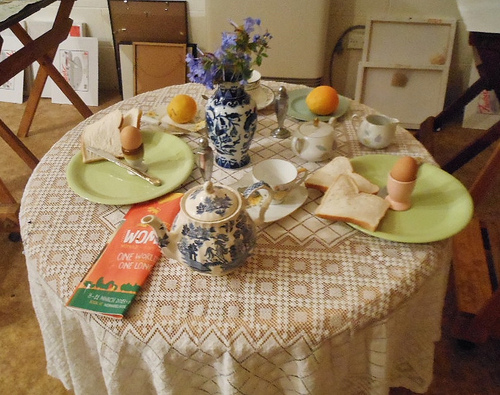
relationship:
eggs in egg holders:
[389, 150, 416, 181] [124, 146, 146, 170]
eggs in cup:
[119, 122, 141, 149] [384, 172, 416, 211]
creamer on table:
[327, 103, 411, 156] [49, 89, 444, 353]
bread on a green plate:
[302, 152, 390, 233] [343, 154, 475, 242]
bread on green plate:
[314, 174, 390, 233] [369, 171, 476, 247]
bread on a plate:
[314, 174, 390, 233] [326, 153, 476, 243]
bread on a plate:
[304, 155, 380, 195] [326, 153, 476, 243]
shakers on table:
[205, 85, 258, 168] [14, 74, 451, 393]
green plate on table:
[355, 152, 479, 241] [149, 209, 439, 344]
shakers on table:
[192, 78, 297, 185] [21, 50, 499, 377]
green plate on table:
[67, 129, 193, 205] [14, 74, 451, 393]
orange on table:
[167, 96, 195, 123] [14, 74, 451, 393]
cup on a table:
[249, 157, 305, 202] [14, 74, 451, 393]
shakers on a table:
[205, 85, 258, 168] [162, 123, 404, 335]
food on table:
[81, 71, 438, 234] [14, 74, 451, 393]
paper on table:
[87, 175, 177, 333] [47, 51, 461, 333]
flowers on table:
[183, 17, 273, 91] [12, 67, 477, 379]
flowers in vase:
[183, 28, 263, 80] [205, 86, 256, 165]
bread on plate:
[295, 153, 402, 240] [321, 145, 481, 255]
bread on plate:
[314, 174, 390, 233] [326, 153, 476, 243]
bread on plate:
[302, 152, 390, 233] [321, 145, 481, 255]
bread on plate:
[70, 100, 144, 160] [55, 118, 204, 216]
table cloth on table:
[18, 33, 468, 366] [14, 74, 451, 393]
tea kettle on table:
[176, 185, 258, 274] [254, 219, 381, 322]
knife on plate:
[76, 139, 166, 199] [59, 114, 197, 212]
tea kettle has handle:
[140, 181, 275, 277] [240, 179, 272, 230]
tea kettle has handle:
[140, 181, 275, 277] [288, 135, 305, 157]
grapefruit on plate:
[305, 84, 339, 114] [289, 85, 311, 118]